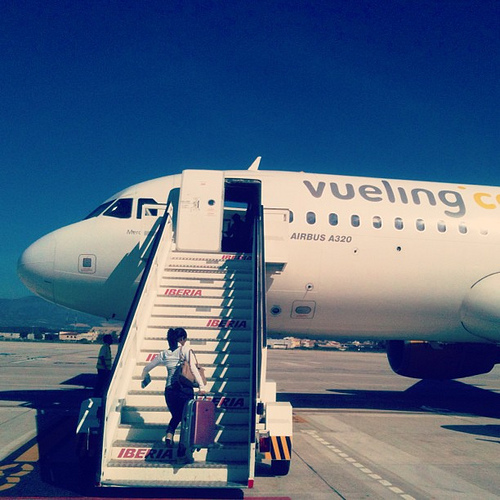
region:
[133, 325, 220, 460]
woman walking up stairs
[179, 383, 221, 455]
luggage in woman's hand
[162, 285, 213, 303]
red word on stair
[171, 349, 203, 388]
bag on woman's shoulder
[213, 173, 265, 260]
open door of plane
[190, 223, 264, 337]
stairs leading to plane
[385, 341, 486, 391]
bottom of jet engine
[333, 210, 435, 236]
windows on side of plane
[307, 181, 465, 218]
gray word on plane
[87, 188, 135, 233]
windows on plane cockpit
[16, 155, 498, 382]
airplane is Airbus A320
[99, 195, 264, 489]
portable stairs at airplane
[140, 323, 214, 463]
woman is carrying suitcase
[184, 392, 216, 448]
hard suitcase is purple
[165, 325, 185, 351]
woman has black hair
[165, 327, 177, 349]
woman's hair in ponytail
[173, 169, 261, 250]
airplane door is open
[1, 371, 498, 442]
airplane casts dark shadow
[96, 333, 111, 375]
worker under white airplane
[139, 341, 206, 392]
woman wearing white shirt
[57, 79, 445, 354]
a large airplane on ground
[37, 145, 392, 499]
a large plane on ground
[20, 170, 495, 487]
a large white iplane on ground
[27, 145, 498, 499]
a large white airplane on ground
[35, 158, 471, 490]
a plane at the airport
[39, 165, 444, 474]
an airplane at airport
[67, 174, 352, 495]
stairs going to airplane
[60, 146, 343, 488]
a woman walking up the stairs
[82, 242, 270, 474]
a woman walking up the stairs with suitcase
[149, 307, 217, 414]
a woman with her hair up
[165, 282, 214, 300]
the word IBERIA written on the steps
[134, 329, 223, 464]
woman carrying luggage walking up steps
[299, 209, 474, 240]
small windows for passengers to look out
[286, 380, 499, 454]
the planes shadow on the ground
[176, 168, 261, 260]
open door of the plane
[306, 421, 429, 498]
white painted broken line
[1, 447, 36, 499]
the number 8 painted on the cement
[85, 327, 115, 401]
a person walking under the plane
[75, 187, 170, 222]
front windows of the plane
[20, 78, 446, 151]
clear blue sky with no clouds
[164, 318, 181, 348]
Person has black hair.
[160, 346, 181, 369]
Person is wearing white shirt.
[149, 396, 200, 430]
Person is wearing dark pants.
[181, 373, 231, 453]
Person is carrying suitcase.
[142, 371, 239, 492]
Person is walking up stairs on to plane.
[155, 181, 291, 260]
Door on plane is open.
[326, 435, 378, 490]
White lines marking ground.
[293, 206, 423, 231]
Windows a long the side of plane.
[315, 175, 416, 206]
Gray writing on side of plane.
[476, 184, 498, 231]
Yellow writing on side of plane.